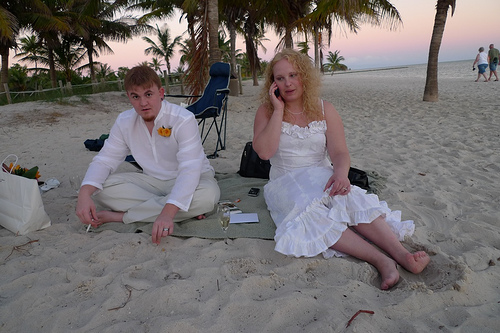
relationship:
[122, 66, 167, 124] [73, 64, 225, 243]
head of man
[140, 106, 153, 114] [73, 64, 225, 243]
mouth of man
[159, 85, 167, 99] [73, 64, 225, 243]
ear of man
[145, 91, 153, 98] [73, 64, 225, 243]
eye of man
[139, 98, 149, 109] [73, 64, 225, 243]
nose of man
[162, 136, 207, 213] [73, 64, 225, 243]
arm of man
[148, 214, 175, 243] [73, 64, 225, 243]
hand of man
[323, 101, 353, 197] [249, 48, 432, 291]
arm of woman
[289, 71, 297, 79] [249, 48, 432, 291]
eye of woman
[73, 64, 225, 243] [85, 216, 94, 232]
man holding cigarette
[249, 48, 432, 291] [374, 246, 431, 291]
woman has feet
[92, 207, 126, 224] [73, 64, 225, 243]
foot of man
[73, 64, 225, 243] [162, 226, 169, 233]
man wearing ring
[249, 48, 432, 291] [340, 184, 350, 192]
woman wearing ring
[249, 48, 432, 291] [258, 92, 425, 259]
woman wearing dress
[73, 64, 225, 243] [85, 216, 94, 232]
man has cigarette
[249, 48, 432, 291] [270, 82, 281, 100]
woman holding phone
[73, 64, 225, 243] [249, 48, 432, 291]
man with woman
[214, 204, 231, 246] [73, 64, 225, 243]
flute near man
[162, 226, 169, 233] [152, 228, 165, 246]
ring on finger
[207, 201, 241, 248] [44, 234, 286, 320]
flute sitting on sand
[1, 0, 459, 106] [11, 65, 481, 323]
palm trees on beach